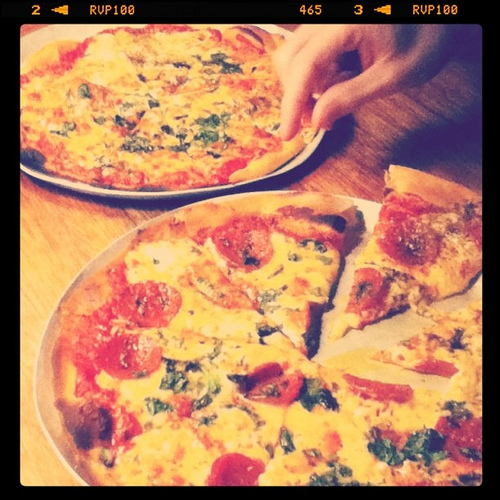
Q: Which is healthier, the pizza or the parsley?
A: The parsley is healthier than the pizza.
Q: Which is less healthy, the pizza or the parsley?
A: The pizza is less healthy than the parsley.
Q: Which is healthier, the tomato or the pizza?
A: The tomato is healthier than the pizza.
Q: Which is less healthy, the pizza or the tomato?
A: The pizza is less healthy than the tomato.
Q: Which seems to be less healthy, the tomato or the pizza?
A: The pizza is less healthy than the tomato.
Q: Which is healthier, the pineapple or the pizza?
A: The pineapple is healthier than the pizza.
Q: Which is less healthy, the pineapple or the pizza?
A: The pizza is less healthy than the pineapple.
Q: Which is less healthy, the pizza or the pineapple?
A: The pizza is less healthy than the pineapple.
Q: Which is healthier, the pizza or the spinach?
A: The spinach is healthier than the pizza.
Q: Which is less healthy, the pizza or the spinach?
A: The pizza is less healthy than the spinach.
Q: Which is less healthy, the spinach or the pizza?
A: The pizza is less healthy than the spinach.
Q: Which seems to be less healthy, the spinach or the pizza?
A: The pizza is less healthy than the spinach.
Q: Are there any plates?
A: Yes, there is a plate.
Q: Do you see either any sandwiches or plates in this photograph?
A: Yes, there is a plate.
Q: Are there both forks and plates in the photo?
A: No, there is a plate but no forks.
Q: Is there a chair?
A: No, there are no chairs.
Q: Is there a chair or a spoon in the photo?
A: No, there are no chairs or spoons.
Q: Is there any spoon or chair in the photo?
A: No, there are no chairs or spoons.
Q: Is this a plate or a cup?
A: This is a plate.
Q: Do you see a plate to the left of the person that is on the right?
A: Yes, there is a plate to the left of the person.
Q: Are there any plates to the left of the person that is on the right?
A: Yes, there is a plate to the left of the person.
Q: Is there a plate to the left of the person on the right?
A: Yes, there is a plate to the left of the person.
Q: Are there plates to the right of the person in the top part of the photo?
A: No, the plate is to the left of the person.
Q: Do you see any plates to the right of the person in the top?
A: No, the plate is to the left of the person.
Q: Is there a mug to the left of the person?
A: No, there is a plate to the left of the person.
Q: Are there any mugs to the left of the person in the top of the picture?
A: No, there is a plate to the left of the person.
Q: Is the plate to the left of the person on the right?
A: Yes, the plate is to the left of the person.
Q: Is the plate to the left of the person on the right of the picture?
A: Yes, the plate is to the left of the person.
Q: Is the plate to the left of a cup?
A: No, the plate is to the left of the person.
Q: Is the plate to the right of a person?
A: No, the plate is to the left of a person.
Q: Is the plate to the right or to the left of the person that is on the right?
A: The plate is to the left of the person.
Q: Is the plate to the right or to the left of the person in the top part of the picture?
A: The plate is to the left of the person.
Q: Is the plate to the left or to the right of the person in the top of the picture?
A: The plate is to the left of the person.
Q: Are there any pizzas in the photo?
A: Yes, there is a pizza.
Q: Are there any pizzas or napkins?
A: Yes, there is a pizza.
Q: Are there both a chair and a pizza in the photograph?
A: No, there is a pizza but no chairs.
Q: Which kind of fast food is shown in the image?
A: The fast food is a pizza.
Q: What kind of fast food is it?
A: The food is a pizza.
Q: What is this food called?
A: This is a pizza.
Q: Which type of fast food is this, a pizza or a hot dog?
A: This is a pizza.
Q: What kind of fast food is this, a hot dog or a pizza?
A: This is a pizza.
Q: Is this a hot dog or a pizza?
A: This is a pizza.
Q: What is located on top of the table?
A: The pizza is on top of the table.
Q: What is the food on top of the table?
A: The food is a pizza.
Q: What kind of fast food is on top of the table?
A: The food is a pizza.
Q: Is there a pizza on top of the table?
A: Yes, there is a pizza on top of the table.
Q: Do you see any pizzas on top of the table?
A: Yes, there is a pizza on top of the table.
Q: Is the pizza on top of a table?
A: Yes, the pizza is on top of a table.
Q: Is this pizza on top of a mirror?
A: No, the pizza is on top of a table.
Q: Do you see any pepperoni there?
A: Yes, there is pepperoni.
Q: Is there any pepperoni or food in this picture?
A: Yes, there is pepperoni.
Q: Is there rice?
A: No, there is no rice.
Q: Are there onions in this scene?
A: Yes, there is an onion.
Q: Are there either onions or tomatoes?
A: Yes, there is an onion.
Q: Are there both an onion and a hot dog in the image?
A: No, there is an onion but no hot dogs.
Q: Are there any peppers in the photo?
A: No, there are no peppers.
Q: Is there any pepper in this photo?
A: No, there are no peppers.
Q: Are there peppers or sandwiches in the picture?
A: No, there are no peppers or sandwiches.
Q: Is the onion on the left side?
A: Yes, the onion is on the left of the image.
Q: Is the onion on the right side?
A: No, the onion is on the left of the image.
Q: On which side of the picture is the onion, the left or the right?
A: The onion is on the left of the image.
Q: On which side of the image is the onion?
A: The onion is on the left of the image.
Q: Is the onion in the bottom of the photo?
A: Yes, the onion is in the bottom of the image.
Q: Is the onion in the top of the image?
A: No, the onion is in the bottom of the image.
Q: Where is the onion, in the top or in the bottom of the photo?
A: The onion is in the bottom of the image.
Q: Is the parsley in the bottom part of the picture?
A: Yes, the parsley is in the bottom of the image.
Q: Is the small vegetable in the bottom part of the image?
A: Yes, the parsley is in the bottom of the image.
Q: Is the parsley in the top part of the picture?
A: No, the parsley is in the bottom of the image.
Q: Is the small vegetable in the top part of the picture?
A: No, the parsley is in the bottom of the image.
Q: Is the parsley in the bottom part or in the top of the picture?
A: The parsley is in the bottom of the image.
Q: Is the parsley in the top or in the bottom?
A: The parsley is in the bottom of the image.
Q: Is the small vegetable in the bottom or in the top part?
A: The parsley is in the bottom of the image.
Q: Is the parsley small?
A: Yes, the parsley is small.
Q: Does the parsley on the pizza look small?
A: Yes, the parsley is small.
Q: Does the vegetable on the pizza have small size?
A: Yes, the parsley is small.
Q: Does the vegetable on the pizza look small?
A: Yes, the parsley is small.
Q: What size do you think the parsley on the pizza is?
A: The parsley is small.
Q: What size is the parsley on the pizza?
A: The parsley is small.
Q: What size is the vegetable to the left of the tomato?
A: The parsley is small.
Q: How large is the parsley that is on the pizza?
A: The parsley is small.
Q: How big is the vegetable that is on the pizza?
A: The parsley is small.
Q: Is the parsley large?
A: No, the parsley is small.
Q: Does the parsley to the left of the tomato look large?
A: No, the parsley is small.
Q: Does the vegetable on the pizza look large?
A: No, the parsley is small.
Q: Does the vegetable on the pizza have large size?
A: No, the parsley is small.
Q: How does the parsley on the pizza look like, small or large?
A: The parsley is small.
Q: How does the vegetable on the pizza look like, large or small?
A: The parsley is small.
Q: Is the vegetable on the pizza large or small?
A: The parsley is small.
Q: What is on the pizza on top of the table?
A: The parsley is on the pizza.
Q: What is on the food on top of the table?
A: The parsley is on the pizza.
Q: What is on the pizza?
A: The parsley is on the pizza.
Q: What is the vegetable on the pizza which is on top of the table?
A: The vegetable is parsley.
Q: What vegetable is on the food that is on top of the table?
A: The vegetable is parsley.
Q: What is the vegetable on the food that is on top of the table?
A: The vegetable is parsley.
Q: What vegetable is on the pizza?
A: The vegetable is parsley.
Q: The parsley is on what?
A: The parsley is on the pizza.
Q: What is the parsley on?
A: The parsley is on the pizza.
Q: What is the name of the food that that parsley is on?
A: The food is a pizza.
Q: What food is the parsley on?
A: The parsley is on the pizza.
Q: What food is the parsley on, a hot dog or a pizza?
A: The parsley is on a pizza.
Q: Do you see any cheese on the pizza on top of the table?
A: No, there is parsley on the pizza.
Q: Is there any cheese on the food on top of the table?
A: No, there is parsley on the pizza.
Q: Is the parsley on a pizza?
A: Yes, the parsley is on a pizza.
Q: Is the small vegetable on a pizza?
A: Yes, the parsley is on a pizza.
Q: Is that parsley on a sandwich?
A: No, the parsley is on a pizza.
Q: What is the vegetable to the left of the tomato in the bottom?
A: The vegetable is parsley.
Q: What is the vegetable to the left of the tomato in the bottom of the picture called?
A: The vegetable is parsley.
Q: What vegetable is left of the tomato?
A: The vegetable is parsley.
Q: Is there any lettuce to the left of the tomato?
A: No, there is parsley to the left of the tomato.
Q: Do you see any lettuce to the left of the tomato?
A: No, there is parsley to the left of the tomato.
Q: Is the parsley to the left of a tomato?
A: Yes, the parsley is to the left of a tomato.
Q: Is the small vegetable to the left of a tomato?
A: Yes, the parsley is to the left of a tomato.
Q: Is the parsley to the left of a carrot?
A: No, the parsley is to the left of a tomato.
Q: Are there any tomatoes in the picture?
A: Yes, there is a tomato.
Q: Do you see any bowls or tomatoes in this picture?
A: Yes, there is a tomato.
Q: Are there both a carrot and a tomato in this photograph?
A: No, there is a tomato but no carrots.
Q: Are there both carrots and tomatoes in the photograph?
A: No, there is a tomato but no carrots.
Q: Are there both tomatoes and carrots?
A: No, there is a tomato but no carrots.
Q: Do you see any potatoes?
A: No, there are no potatoes.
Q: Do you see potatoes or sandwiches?
A: No, there are no potatoes or sandwiches.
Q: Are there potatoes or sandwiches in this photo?
A: No, there are no potatoes or sandwiches.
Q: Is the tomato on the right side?
A: Yes, the tomato is on the right of the image.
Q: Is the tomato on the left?
A: No, the tomato is on the right of the image.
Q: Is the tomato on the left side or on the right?
A: The tomato is on the right of the image.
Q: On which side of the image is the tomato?
A: The tomato is on the right of the image.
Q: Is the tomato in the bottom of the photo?
A: Yes, the tomato is in the bottom of the image.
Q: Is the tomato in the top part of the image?
A: No, the tomato is in the bottom of the image.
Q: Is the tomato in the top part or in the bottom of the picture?
A: The tomato is in the bottom of the image.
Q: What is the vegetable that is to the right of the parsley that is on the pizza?
A: The vegetable is a tomato.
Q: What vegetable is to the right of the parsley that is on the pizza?
A: The vegetable is a tomato.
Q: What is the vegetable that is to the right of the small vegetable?
A: The vegetable is a tomato.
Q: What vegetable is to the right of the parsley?
A: The vegetable is a tomato.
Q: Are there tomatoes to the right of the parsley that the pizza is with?
A: Yes, there is a tomato to the right of the parsley.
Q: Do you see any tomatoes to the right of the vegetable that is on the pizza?
A: Yes, there is a tomato to the right of the parsley.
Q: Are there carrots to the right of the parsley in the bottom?
A: No, there is a tomato to the right of the parsley.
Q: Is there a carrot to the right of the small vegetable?
A: No, there is a tomato to the right of the parsley.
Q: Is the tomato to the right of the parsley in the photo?
A: Yes, the tomato is to the right of the parsley.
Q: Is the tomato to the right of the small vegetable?
A: Yes, the tomato is to the right of the parsley.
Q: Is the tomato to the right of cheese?
A: No, the tomato is to the right of the parsley.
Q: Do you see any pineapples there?
A: Yes, there is a pineapple.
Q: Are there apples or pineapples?
A: Yes, there is a pineapple.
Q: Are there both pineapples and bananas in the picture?
A: No, there is a pineapple but no bananas.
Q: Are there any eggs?
A: No, there are no eggs.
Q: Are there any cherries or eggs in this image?
A: No, there are no eggs or cherries.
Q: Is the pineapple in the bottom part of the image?
A: Yes, the pineapple is in the bottom of the image.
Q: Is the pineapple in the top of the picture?
A: No, the pineapple is in the bottom of the image.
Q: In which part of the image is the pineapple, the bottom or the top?
A: The pineapple is in the bottom of the image.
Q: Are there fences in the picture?
A: No, there are no fences.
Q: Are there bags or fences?
A: No, there are no fences or bags.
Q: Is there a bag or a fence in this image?
A: No, there are no fences or bags.